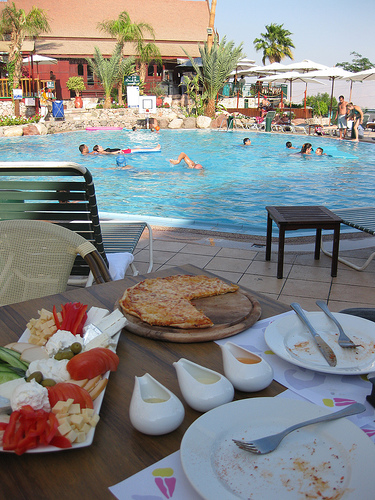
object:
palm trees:
[178, 28, 245, 120]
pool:
[0, 127, 374, 238]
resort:
[0, 0, 214, 98]